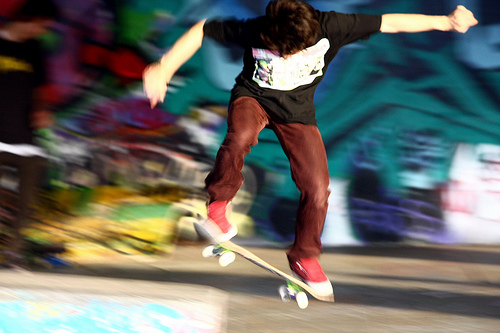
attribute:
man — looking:
[126, 0, 480, 299]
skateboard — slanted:
[178, 219, 347, 310]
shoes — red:
[197, 197, 344, 290]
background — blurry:
[1, 1, 496, 266]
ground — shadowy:
[4, 243, 499, 330]